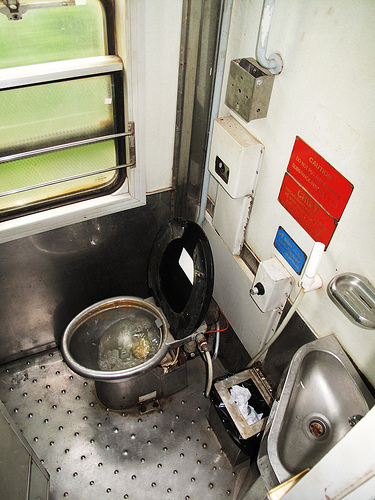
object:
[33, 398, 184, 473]
rivets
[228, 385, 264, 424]
garbage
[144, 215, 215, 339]
seat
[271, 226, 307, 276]
sign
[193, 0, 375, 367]
wall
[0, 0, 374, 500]
toilet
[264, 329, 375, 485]
sink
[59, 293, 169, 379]
bowl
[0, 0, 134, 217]
window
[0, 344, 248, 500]
floor